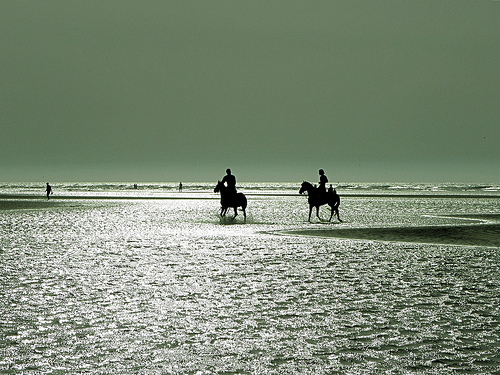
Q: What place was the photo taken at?
A: It was taken at the beach.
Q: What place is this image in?
A: It is at the beach.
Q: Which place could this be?
A: It is a beach.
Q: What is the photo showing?
A: It is showing a beach.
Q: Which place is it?
A: It is a beach.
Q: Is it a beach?
A: Yes, it is a beach.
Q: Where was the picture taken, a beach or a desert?
A: It was taken at a beach.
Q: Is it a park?
A: No, it is a beach.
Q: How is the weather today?
A: It is clear.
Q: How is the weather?
A: It is clear.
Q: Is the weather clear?
A: Yes, it is clear.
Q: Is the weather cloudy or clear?
A: It is clear.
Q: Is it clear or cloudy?
A: It is clear.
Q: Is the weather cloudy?
A: No, it is clear.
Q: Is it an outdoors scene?
A: Yes, it is outdoors.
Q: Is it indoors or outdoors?
A: It is outdoors.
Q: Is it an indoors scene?
A: No, it is outdoors.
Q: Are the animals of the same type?
A: Yes, all the animals are horses.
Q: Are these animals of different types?
A: No, all the animals are horses.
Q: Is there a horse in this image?
A: Yes, there is a horse.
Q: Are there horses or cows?
A: Yes, there is a horse.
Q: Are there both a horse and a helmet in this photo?
A: No, there is a horse but no helmets.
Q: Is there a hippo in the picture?
A: No, there are no hippos.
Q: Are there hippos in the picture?
A: No, there are no hippos.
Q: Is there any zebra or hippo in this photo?
A: No, there are no hippos or zebras.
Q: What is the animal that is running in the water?
A: The animal is a horse.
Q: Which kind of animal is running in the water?
A: The animal is a horse.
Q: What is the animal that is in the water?
A: The animal is a horse.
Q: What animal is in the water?
A: The animal is a horse.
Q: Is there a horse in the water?
A: Yes, there is a horse in the water.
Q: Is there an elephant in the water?
A: No, there is a horse in the water.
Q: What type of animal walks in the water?
A: The animal is a horse.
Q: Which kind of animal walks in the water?
A: The animal is a horse.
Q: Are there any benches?
A: No, there are no benches.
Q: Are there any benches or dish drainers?
A: No, there are no benches or dish drainers.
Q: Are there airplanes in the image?
A: No, there are no airplanes.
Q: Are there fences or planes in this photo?
A: No, there are no planes or fences.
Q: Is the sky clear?
A: Yes, the sky is clear.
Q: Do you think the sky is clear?
A: Yes, the sky is clear.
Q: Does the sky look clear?
A: Yes, the sky is clear.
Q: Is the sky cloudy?
A: No, the sky is clear.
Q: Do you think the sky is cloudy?
A: No, the sky is clear.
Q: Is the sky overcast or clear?
A: The sky is clear.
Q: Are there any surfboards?
A: No, there are no surfboards.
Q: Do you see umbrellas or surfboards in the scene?
A: No, there are no surfboards or umbrellas.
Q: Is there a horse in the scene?
A: Yes, there is a horse.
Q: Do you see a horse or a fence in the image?
A: Yes, there is a horse.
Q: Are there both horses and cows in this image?
A: No, there is a horse but no cows.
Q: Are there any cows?
A: No, there are no cows.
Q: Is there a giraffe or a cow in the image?
A: No, there are no cows or giraffes.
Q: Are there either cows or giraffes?
A: No, there are no cows or giraffes.